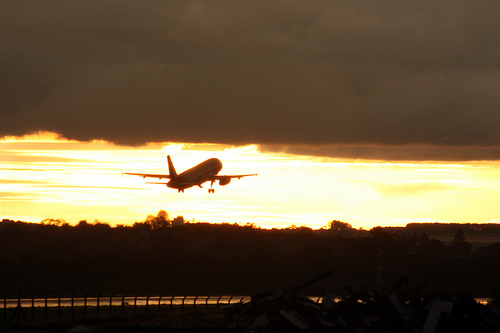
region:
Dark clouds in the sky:
[0, 31, 480, 148]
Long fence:
[1, 277, 348, 320]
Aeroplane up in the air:
[120, 145, 263, 199]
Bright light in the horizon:
[262, 168, 494, 219]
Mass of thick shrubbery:
[10, 221, 397, 281]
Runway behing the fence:
[5, 293, 237, 304]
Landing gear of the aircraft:
[203, 182, 220, 199]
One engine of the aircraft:
[217, 173, 232, 189]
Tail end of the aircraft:
[162, 152, 182, 187]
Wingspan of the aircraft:
[121, 167, 254, 179]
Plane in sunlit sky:
[118, 156, 262, 191]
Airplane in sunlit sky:
[125, 148, 259, 193]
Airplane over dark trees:
[110, 153, 260, 196]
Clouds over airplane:
[3, 3, 498, 158]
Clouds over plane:
[3, 1, 495, 155]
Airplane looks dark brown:
[115, 156, 261, 193]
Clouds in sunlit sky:
[4, 136, 495, 227]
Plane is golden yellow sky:
[4, 131, 496, 221]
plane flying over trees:
[133, 154, 257, 194]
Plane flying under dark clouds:
[118, 154, 268, 194]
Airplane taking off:
[129, 152, 254, 197]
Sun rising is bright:
[6, 131, 498, 248]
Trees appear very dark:
[3, 217, 498, 312]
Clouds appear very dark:
[4, 4, 498, 166]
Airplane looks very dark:
[117, 145, 259, 203]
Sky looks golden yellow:
[4, 138, 497, 233]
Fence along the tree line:
[6, 283, 357, 312]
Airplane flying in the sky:
[119, 151, 256, 201]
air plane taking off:
[113, 109, 248, 208]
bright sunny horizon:
[21, 119, 481, 251]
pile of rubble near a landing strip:
[220, 261, 471, 323]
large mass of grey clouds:
[14, 21, 485, 148]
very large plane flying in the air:
[123, 139, 264, 222]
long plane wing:
[121, 166, 173, 185]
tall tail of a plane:
[154, 143, 199, 193]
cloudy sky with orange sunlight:
[9, 25, 487, 284]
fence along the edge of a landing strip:
[10, 273, 248, 322]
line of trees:
[20, 196, 475, 296]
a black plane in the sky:
[114, 148, 259, 202]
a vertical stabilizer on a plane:
[161, 146, 181, 180]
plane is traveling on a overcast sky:
[0, 4, 496, 208]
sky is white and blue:
[1, 2, 488, 222]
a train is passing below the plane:
[3, 280, 494, 321]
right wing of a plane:
[199, 166, 256, 181]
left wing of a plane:
[120, 168, 170, 183]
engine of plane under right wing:
[214, 176, 234, 188]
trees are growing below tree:
[4, 209, 498, 276]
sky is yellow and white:
[0, 139, 496, 229]